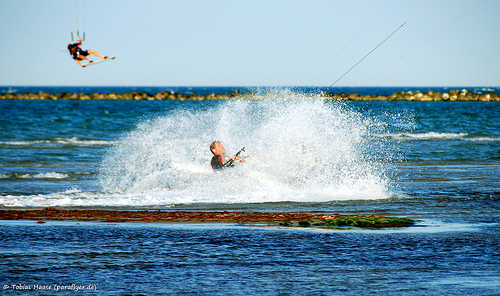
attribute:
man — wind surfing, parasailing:
[63, 33, 116, 70]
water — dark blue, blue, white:
[1, 86, 498, 292]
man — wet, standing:
[208, 136, 248, 173]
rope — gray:
[236, 2, 436, 155]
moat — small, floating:
[1, 204, 419, 233]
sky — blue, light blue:
[1, 0, 499, 86]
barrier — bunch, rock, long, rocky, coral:
[0, 85, 500, 109]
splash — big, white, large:
[94, 84, 423, 209]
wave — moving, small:
[0, 134, 125, 151]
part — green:
[243, 214, 417, 232]